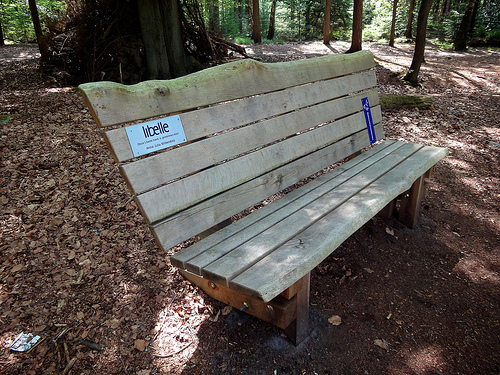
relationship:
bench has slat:
[70, 42, 459, 369] [150, 138, 448, 259]